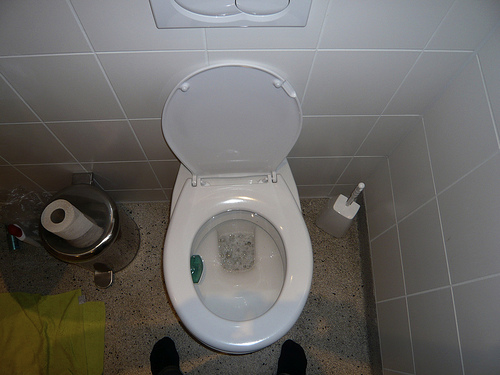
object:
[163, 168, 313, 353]
seat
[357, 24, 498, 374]
wall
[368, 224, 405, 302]
tile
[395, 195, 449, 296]
tile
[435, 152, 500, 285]
tile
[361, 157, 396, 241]
tile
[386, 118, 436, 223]
tile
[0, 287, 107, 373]
towel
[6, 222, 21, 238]
top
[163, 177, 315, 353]
bowl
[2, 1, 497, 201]
wall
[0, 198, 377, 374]
floor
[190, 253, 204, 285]
bowl cleaner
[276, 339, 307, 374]
feet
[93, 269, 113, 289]
step latch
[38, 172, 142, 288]
can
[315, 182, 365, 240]
brush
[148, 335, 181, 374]
sock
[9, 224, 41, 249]
item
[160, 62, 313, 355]
toilet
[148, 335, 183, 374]
feet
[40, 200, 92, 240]
toilet paper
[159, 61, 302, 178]
lid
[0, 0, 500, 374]
bathroom